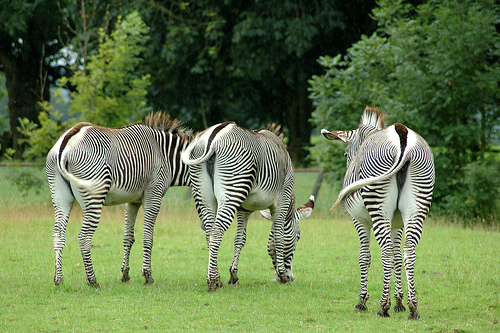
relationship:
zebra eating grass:
[178, 121, 300, 292] [256, 280, 322, 307]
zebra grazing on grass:
[180, 120, 309, 300] [10, 220, 495, 331]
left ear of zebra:
[321, 126, 350, 146] [318, 109, 436, 317]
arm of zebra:
[269, 182, 303, 286] [179, 98, 325, 316]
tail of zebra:
[52, 127, 107, 194] [45, 108, 193, 289]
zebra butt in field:
[45, 125, 107, 205] [2, 167, 497, 329]